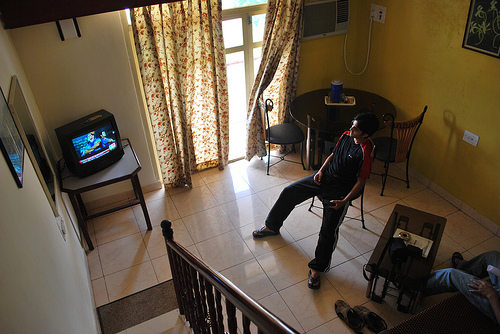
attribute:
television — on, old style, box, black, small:
[54, 108, 125, 179]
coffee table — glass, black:
[365, 201, 446, 313]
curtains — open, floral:
[126, 1, 301, 190]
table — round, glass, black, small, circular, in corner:
[291, 87, 396, 173]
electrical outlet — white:
[369, 2, 388, 26]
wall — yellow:
[354, 0, 499, 237]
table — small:
[56, 136, 153, 251]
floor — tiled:
[79, 144, 498, 333]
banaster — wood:
[161, 220, 304, 333]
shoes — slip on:
[333, 296, 387, 332]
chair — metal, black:
[260, 94, 306, 177]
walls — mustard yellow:
[290, 0, 498, 227]